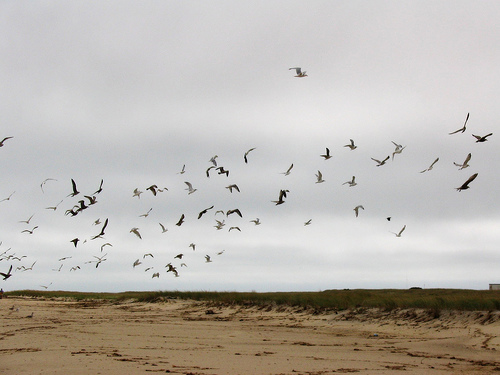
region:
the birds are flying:
[96, 105, 373, 367]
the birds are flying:
[173, 100, 355, 275]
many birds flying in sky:
[1, 106, 458, 271]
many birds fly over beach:
[5, 126, 437, 266]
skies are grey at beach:
[25, 24, 452, 280]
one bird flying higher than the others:
[276, 37, 330, 95]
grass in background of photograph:
[12, 253, 484, 336]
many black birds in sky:
[16, 133, 461, 255]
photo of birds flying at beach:
[12, 148, 473, 372]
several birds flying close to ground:
[1, 247, 221, 298]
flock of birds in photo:
[10, 116, 452, 274]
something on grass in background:
[394, 281, 446, 304]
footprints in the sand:
[80, 342, 180, 369]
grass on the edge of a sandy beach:
[0, 300, 490, 329]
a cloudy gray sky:
[0, 0, 495, 285]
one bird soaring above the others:
[280, 60, 310, 80]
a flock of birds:
[0, 105, 495, 280]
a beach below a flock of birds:
[0, 290, 495, 370]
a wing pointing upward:
[66, 172, 76, 192]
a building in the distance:
[485, 277, 496, 287]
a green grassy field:
[1, 280, 494, 305]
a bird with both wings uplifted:
[385, 222, 416, 238]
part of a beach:
[315, 322, 340, 344]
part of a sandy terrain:
[144, 324, 191, 365]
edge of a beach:
[238, 305, 248, 320]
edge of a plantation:
[387, 302, 416, 327]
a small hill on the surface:
[136, 281, 173, 305]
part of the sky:
[190, 61, 215, 108]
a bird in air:
[379, 158, 387, 168]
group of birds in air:
[142, 171, 328, 235]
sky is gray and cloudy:
[0, 1, 498, 290]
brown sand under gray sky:
[0, 295, 499, 374]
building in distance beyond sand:
[490, 283, 498, 291]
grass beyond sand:
[7, 289, 498, 315]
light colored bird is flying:
[289, 66, 311, 78]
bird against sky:
[388, 223, 408, 240]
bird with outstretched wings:
[91, 179, 107, 195]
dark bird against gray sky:
[454, 172, 480, 193]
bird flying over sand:
[203, 253, 213, 266]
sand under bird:
[99, 242, 111, 251]